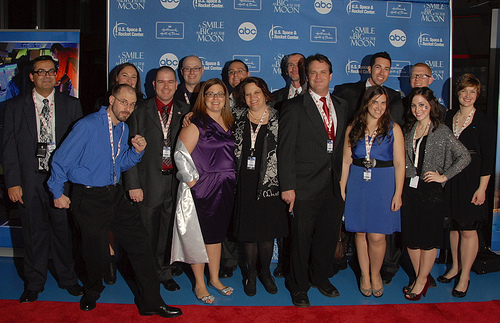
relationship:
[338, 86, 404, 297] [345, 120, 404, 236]
woman wearing dress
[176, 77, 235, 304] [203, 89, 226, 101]
woman wearing glasses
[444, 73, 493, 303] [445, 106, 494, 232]
woman wearing dress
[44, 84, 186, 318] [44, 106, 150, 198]
man wearing shirt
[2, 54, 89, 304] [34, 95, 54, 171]
man wearing tie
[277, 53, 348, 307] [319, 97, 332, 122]
man wearing tie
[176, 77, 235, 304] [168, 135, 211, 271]
woman holding wrap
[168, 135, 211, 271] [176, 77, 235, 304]
wrap on woman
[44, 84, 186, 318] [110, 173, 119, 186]
man wearing tag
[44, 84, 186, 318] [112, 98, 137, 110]
man wearing glasses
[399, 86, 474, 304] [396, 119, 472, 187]
woman wearing sweater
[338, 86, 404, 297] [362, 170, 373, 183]
woman wearing tag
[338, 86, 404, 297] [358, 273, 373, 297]
woman wearing sandle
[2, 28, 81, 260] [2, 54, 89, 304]
sign behind man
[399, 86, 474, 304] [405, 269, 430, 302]
woman wearing heels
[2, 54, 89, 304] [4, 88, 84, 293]
man wearing suit